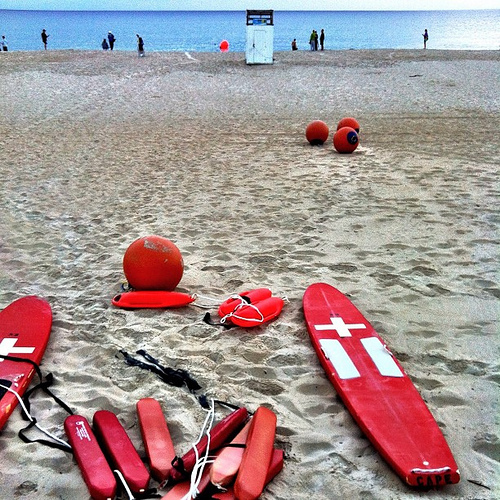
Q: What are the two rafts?
A: Lifeguard.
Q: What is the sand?
A: Tan and brown.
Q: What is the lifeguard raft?
A: Red and white.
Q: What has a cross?
A: The lifeguard raft.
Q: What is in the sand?
A: The tracks.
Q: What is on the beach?
A: The life preservers.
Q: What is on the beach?
A: The rescue team's surfboard.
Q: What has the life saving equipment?
A: The beach.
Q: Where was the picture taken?
A: The beach.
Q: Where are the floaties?
A: On the sand.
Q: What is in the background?
A: Ocean.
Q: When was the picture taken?
A: During day hours.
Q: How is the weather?
A: Clear.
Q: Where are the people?
A: On the beach.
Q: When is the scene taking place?
A: Daytime.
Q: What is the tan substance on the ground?
A: Sand.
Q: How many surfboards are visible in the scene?
A: Two.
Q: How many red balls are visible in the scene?
A: Four.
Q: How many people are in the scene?
A: Ten.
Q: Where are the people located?
A: Beach.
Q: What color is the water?
A: Blue.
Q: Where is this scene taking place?
A: On a beach.